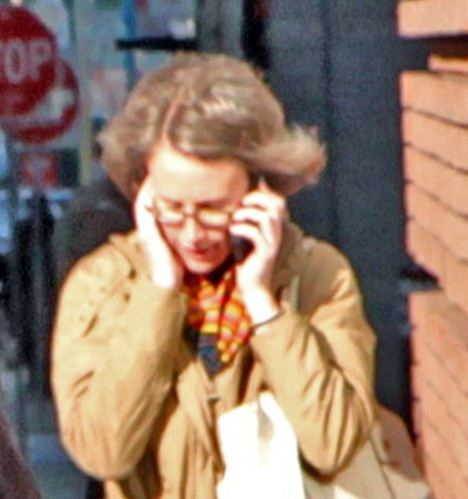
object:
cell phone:
[227, 174, 276, 264]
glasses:
[146, 203, 233, 228]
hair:
[91, 51, 329, 208]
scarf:
[181, 274, 253, 373]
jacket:
[47, 216, 376, 499]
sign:
[0, 35, 55, 85]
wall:
[393, 2, 466, 470]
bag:
[207, 386, 433, 499]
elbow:
[73, 444, 144, 485]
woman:
[48, 49, 377, 498]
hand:
[131, 175, 185, 293]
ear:
[140, 171, 149, 192]